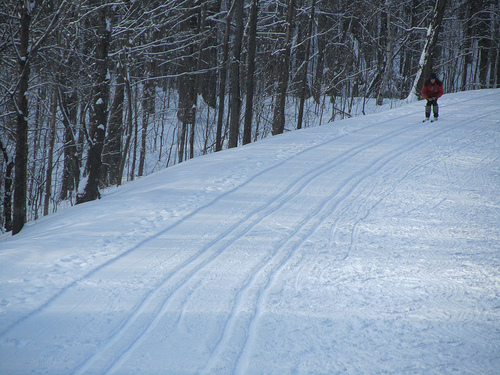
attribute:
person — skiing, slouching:
[422, 73, 443, 123]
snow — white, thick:
[2, 86, 499, 375]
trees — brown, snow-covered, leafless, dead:
[2, 0, 498, 239]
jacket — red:
[423, 80, 445, 98]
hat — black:
[429, 72, 437, 80]